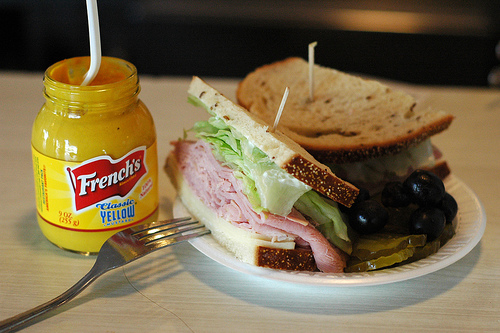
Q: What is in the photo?
A: Food.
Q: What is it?
A: A sandwich.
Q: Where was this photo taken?
A: In a home.